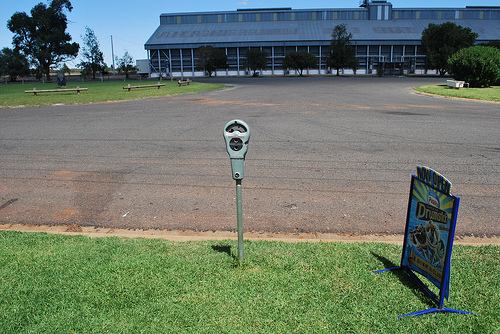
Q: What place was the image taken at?
A: It was taken at the road.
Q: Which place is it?
A: It is a road.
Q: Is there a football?
A: No, there are no footballs.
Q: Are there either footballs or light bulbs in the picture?
A: No, there are no footballs or light bulbs.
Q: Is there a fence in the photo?
A: No, there are no fences.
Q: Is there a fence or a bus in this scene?
A: No, there are no fences or buses.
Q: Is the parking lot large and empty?
A: Yes, the parking lot is large and empty.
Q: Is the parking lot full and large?
A: No, the parking lot is large but empty.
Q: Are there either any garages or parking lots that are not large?
A: No, there is a parking lot but it is large.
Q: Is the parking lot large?
A: Yes, the parking lot is large.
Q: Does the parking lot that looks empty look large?
A: Yes, the parking lot is large.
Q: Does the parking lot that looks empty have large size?
A: Yes, the parking lot is large.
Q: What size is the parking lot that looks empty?
A: The parking lot is large.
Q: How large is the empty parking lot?
A: The parking lot is large.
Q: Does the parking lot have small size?
A: No, the parking lot is large.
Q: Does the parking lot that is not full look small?
A: No, the parking lot is large.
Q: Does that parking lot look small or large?
A: The parking lot is large.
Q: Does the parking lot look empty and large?
A: Yes, the parking lot is empty and large.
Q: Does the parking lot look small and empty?
A: No, the parking lot is empty but large.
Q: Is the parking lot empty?
A: Yes, the parking lot is empty.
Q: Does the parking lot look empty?
A: Yes, the parking lot is empty.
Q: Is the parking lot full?
A: No, the parking lot is empty.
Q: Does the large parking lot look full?
A: No, the parking lot is empty.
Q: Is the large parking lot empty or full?
A: The parking lot is empty.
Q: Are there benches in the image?
A: Yes, there is a bench.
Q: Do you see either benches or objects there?
A: Yes, there is a bench.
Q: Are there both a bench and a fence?
A: No, there is a bench but no fences.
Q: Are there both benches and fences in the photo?
A: No, there is a bench but no fences.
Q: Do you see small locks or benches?
A: Yes, there is a small bench.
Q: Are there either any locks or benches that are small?
A: Yes, the bench is small.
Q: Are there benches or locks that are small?
A: Yes, the bench is small.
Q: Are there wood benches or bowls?
A: Yes, there is a wood bench.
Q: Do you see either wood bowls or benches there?
A: Yes, there is a wood bench.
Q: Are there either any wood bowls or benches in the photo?
A: Yes, there is a wood bench.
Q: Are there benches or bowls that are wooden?
A: Yes, the bench is wooden.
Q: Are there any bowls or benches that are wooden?
A: Yes, the bench is wooden.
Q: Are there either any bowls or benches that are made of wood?
A: Yes, the bench is made of wood.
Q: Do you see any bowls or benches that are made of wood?
A: Yes, the bench is made of wood.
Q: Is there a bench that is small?
A: Yes, there is a small bench.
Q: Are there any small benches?
A: Yes, there is a small bench.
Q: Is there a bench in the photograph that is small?
A: Yes, there is a bench that is small.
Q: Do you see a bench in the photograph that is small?
A: Yes, there is a bench that is small.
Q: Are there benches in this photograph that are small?
A: Yes, there is a bench that is small.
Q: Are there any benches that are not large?
A: Yes, there is a small bench.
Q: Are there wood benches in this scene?
A: Yes, there is a wood bench.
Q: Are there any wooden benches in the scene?
A: Yes, there is a wood bench.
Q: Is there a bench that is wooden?
A: Yes, there is a bench that is wooden.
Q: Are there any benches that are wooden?
A: Yes, there is a bench that is wooden.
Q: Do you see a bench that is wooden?
A: Yes, there is a bench that is wooden.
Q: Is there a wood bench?
A: Yes, there is a bench that is made of wood.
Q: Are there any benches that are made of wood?
A: Yes, there is a bench that is made of wood.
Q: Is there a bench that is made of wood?
A: Yes, there is a bench that is made of wood.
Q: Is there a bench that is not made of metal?
A: Yes, there is a bench that is made of wood.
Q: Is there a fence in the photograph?
A: No, there are no fences.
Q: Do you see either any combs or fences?
A: No, there are no fences or combs.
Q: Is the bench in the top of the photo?
A: Yes, the bench is in the top of the image.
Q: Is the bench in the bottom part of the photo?
A: No, the bench is in the top of the image.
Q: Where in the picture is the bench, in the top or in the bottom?
A: The bench is in the top of the image.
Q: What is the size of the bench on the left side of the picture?
A: The bench is small.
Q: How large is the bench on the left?
A: The bench is small.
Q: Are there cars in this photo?
A: No, there are no cars.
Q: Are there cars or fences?
A: No, there are no cars or fences.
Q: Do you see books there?
A: No, there are no books.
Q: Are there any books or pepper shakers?
A: No, there are no books or pepper shakers.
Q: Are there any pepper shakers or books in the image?
A: No, there are no books or pepper shakers.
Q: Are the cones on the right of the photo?
A: Yes, the cones are on the right of the image.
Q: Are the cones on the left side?
A: No, the cones are on the right of the image.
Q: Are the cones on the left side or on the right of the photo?
A: The cones are on the right of the image.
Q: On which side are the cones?
A: The cones are on the right of the image.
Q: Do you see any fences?
A: No, there are no fences.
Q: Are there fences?
A: No, there are no fences.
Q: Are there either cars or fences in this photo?
A: No, there are no fences or cars.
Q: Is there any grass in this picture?
A: Yes, there is grass.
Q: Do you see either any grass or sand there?
A: Yes, there is grass.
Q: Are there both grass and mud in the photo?
A: No, there is grass but no mud.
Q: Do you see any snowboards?
A: No, there are no snowboards.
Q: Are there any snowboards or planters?
A: No, there are no snowboards or planters.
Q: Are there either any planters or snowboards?
A: No, there are no snowboards or planters.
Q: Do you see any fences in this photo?
A: No, there are no fences.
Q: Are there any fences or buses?
A: No, there are no fences or buses.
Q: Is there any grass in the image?
A: Yes, there is grass.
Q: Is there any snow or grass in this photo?
A: Yes, there is grass.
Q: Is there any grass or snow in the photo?
A: Yes, there is grass.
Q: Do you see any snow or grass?
A: Yes, there is grass.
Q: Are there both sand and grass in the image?
A: No, there is grass but no sand.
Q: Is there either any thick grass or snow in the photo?
A: Yes, there is thick grass.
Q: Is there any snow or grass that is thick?
A: Yes, the grass is thick.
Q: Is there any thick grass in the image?
A: Yes, there is thick grass.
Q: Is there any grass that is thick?
A: Yes, there is grass that is thick.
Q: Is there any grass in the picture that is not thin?
A: Yes, there is thick grass.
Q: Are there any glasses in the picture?
A: No, there are no glasses.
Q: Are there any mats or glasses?
A: No, there are no glasses or mats.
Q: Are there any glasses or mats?
A: No, there are no glasses or mats.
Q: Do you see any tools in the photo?
A: No, there are no tools.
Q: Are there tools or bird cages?
A: No, there are no tools or bird cages.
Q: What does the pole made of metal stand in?
A: The pole stands in the grass.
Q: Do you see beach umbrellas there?
A: No, there are no beach umbrellas.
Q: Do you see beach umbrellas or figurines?
A: No, there are no beach umbrellas or figurines.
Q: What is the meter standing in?
A: The meter is standing in the grass.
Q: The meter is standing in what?
A: The meter is standing in the grass.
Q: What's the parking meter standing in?
A: The meter is standing in the grass.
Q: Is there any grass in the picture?
A: Yes, there is grass.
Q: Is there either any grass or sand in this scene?
A: Yes, there is grass.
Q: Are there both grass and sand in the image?
A: No, there is grass but no sand.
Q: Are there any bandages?
A: No, there are no bandages.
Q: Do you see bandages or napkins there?
A: No, there are no bandages or napkins.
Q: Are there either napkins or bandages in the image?
A: No, there are no bandages or napkins.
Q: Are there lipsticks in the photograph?
A: No, there are no lipsticks.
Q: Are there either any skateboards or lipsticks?
A: No, there are no lipsticks or skateboards.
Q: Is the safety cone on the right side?
A: Yes, the safety cone is on the right of the image.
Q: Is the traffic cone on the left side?
A: No, the traffic cone is on the right of the image.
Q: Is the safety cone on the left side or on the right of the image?
A: The safety cone is on the right of the image.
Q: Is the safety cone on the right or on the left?
A: The safety cone is on the right of the image.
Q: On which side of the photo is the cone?
A: The cone is on the right of the image.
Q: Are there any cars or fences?
A: No, there are no fences or cars.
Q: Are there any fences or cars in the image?
A: No, there are no fences or cars.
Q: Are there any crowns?
A: No, there are no crowns.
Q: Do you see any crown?
A: No, there are no crowns.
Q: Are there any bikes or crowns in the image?
A: No, there are no crowns or bikes.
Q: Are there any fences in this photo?
A: No, there are no fences.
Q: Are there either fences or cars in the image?
A: No, there are no fences or cars.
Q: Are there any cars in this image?
A: No, there are no cars.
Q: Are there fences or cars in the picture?
A: No, there are no cars or fences.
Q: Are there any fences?
A: No, there are no fences.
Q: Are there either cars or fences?
A: No, there are no fences or cars.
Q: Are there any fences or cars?
A: No, there are no fences or cars.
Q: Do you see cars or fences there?
A: No, there are no fences or cars.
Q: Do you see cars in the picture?
A: No, there are no cars.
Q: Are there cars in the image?
A: No, there are no cars.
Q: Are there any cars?
A: No, there are no cars.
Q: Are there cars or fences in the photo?
A: No, there are no cars or fences.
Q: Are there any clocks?
A: No, there are no clocks.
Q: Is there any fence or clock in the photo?
A: No, there are no clocks or fences.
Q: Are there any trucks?
A: No, there are no trucks.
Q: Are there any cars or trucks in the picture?
A: No, there are no trucks or cars.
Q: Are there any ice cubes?
A: No, there are no ice cubes.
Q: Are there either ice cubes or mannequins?
A: No, there are no ice cubes or mannequins.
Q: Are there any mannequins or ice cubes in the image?
A: No, there are no ice cubes or mannequins.